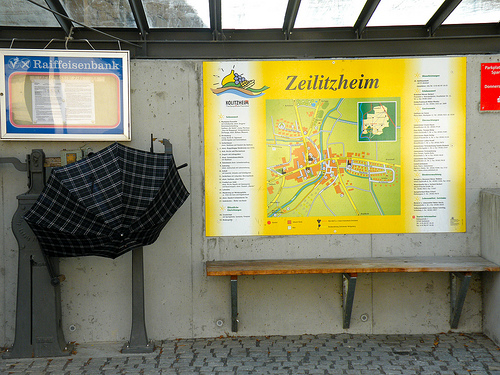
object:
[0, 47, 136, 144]
glass case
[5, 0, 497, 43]
roof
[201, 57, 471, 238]
poster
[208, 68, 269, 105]
logo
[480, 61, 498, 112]
red sign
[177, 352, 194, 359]
cobblestone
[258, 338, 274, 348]
cobblestone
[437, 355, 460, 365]
cobblestone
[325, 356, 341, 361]
cobblestone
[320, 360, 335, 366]
cobblestone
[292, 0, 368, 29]
glass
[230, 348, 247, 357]
bricks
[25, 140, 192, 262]
umberella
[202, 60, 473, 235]
map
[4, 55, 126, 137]
poster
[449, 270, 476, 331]
bar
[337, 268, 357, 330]
bar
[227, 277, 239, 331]
bar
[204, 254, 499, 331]
bench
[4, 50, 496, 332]
wall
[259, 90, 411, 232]
map